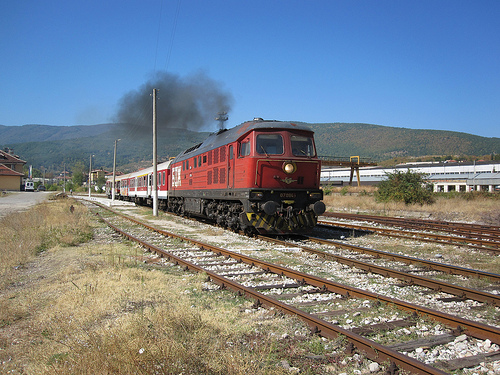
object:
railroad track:
[76, 204, 168, 240]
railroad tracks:
[315, 288, 499, 372]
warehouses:
[323, 163, 499, 196]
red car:
[167, 114, 331, 240]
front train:
[240, 114, 329, 242]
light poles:
[106, 135, 122, 205]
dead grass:
[0, 288, 94, 371]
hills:
[331, 127, 496, 151]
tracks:
[67, 193, 497, 373]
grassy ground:
[0, 269, 150, 375]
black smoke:
[101, 63, 237, 149]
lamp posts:
[133, 82, 183, 219]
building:
[0, 138, 32, 193]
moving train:
[104, 117, 323, 236]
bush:
[371, 168, 441, 206]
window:
[288, 134, 318, 159]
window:
[253, 129, 289, 157]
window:
[238, 138, 252, 160]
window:
[228, 144, 235, 161]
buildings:
[427, 171, 479, 195]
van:
[20, 176, 38, 194]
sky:
[349, 1, 500, 106]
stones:
[328, 257, 365, 278]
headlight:
[281, 158, 298, 177]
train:
[96, 113, 327, 239]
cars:
[117, 156, 165, 205]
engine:
[170, 118, 330, 240]